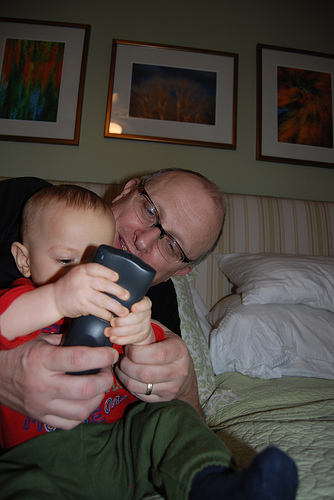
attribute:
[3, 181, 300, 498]
baby — looking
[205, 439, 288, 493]
blue sock — navy blue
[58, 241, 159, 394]
remote — black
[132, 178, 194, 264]
glasses — reading glasses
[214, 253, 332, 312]
pillow — stacked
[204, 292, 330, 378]
pillow — stacked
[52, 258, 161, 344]
hand — baby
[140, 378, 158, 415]
ring — wedding ring 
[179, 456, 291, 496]
socks — blue